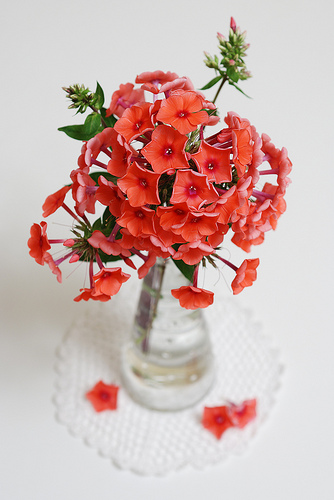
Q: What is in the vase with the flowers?
A: Water.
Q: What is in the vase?
A: Flowers.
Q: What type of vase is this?
A: Glass.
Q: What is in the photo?
A: Flowers.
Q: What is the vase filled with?
A: Water.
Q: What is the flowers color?
A: Red.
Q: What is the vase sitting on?
A: Doily.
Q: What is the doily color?
A: White.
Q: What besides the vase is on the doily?
A: Petals.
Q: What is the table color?
A: White.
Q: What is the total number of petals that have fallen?
A: 3.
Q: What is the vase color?
A: Clear.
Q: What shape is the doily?
A: Round.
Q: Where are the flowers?
A: In a vase.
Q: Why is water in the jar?
A: To nourish the flowers.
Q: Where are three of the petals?
A: On the ground.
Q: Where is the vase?
A: On a doily.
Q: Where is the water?
A: In the vase.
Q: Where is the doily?
A: Under the vase.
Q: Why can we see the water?
A: Because the vase is clear.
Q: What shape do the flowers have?
A: Star.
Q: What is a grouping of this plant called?
A: A bouquet.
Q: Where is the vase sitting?
A: On a table.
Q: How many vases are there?
A: One.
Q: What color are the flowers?
A: Red.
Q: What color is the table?
A: White.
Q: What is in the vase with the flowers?
A: Water.